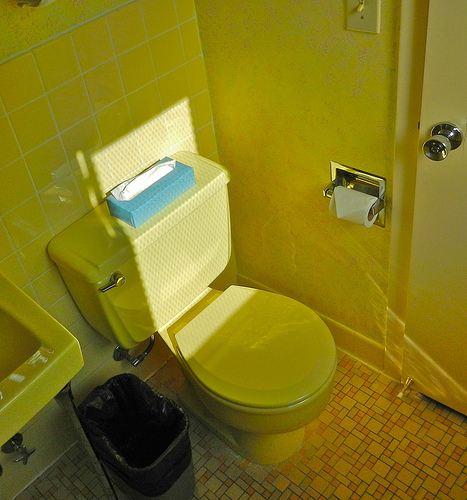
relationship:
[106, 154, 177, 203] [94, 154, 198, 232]
kleenex in box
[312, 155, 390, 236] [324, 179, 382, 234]
dispenser for toilet paper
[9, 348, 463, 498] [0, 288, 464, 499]
tile on floor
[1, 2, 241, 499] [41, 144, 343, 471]
wall behind toilet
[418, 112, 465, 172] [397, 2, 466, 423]
handle on door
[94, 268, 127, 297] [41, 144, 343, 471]
lever on toilet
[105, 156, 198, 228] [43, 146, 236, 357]
box on toilet tank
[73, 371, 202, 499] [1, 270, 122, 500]
garbage can next to sink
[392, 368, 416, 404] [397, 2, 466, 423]
door stopper on door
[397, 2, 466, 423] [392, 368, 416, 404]
door has door stopper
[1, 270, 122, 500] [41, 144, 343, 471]
sink next to toilet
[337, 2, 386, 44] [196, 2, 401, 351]
light switch on wall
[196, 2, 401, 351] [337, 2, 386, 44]
wall has light switch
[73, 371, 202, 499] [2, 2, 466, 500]
garbage can in bathroom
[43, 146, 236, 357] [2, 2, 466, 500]
toilet tank in bathroom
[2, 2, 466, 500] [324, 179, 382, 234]
bathroom has toilet paper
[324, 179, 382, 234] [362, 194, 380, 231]
toilet paper in roll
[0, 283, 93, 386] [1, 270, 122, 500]
edge of sink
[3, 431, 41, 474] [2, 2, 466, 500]
tap in bathroom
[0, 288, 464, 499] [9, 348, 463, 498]
floor has tile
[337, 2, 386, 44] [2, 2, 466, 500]
light switch in bathroom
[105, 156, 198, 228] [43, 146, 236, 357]
box above toilet tank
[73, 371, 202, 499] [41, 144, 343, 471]
garbage can near toilet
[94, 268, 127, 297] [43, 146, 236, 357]
lever on toilet tank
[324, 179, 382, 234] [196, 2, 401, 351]
toilet paper on wall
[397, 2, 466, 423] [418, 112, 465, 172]
door has handle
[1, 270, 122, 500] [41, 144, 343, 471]
sink near toilet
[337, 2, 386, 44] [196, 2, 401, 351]
light switch attached to wall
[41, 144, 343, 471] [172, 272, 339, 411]
toilet has cover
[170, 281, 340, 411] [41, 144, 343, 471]
toilet lid on toilet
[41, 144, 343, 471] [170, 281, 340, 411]
toilet has toilet lid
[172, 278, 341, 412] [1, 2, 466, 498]
toilet seat in photo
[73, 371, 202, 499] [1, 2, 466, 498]
garbage can in photo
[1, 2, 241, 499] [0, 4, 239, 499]
wall has tile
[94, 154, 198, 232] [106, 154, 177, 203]
box has kleenex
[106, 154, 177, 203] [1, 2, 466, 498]
kleenex in photo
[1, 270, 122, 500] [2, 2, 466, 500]
sink in bathroom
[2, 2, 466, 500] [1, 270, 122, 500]
bathroom has sink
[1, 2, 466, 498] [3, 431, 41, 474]
photo has tap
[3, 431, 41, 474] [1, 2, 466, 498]
tap in photo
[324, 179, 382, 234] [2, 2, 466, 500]
toilet paper in bathroom